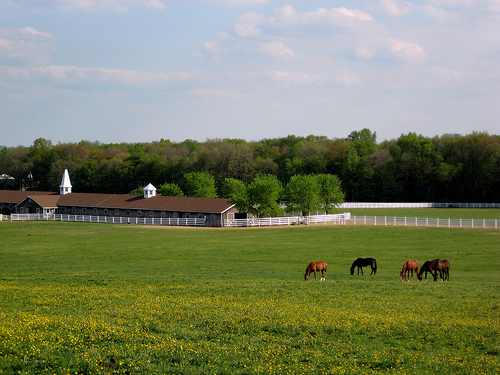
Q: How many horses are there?
A: Five.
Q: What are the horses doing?
A: Grazing.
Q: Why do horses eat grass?
A: It's their diet.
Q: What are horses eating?
A: Grass.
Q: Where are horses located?
A: Stable grounds.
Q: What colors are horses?
A: Brown and black.